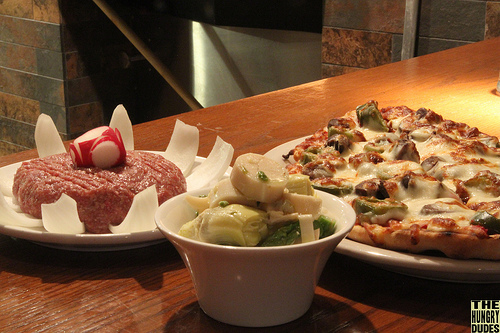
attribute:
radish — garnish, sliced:
[93, 129, 120, 141]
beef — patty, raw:
[85, 183, 111, 202]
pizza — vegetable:
[364, 128, 462, 221]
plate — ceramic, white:
[366, 249, 429, 274]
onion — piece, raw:
[130, 201, 156, 222]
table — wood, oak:
[228, 59, 285, 108]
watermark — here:
[461, 301, 480, 315]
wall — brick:
[7, 51, 62, 99]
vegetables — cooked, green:
[210, 156, 317, 254]